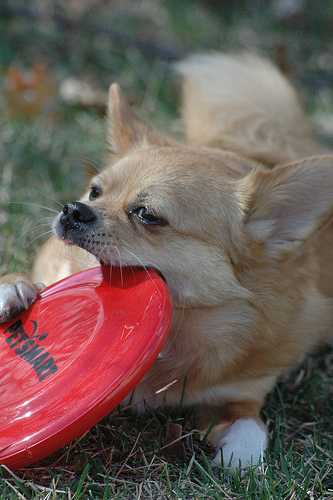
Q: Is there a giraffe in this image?
A: No, there are no giraffes.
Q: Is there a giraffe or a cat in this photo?
A: No, there are no giraffes or cats.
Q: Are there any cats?
A: No, there are no cats.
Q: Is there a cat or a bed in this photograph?
A: No, there are no cats or beds.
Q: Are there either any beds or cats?
A: No, there are no cats or beds.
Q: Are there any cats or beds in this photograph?
A: No, there are no cats or beds.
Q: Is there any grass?
A: Yes, there is grass.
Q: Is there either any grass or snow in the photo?
A: Yes, there is grass.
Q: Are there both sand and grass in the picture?
A: No, there is grass but no sand.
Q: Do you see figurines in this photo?
A: No, there are no figurines.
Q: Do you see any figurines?
A: No, there are no figurines.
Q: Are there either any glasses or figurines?
A: No, there are no figurines or glasses.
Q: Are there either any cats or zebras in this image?
A: No, there are no cats or zebras.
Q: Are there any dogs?
A: Yes, there is a dog.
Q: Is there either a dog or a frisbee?
A: Yes, there is a dog.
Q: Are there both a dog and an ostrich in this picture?
A: No, there is a dog but no ostriches.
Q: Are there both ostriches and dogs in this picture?
A: No, there is a dog but no ostriches.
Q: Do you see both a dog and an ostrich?
A: No, there is a dog but no ostriches.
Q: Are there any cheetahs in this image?
A: No, there are no cheetahs.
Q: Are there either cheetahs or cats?
A: No, there are no cheetahs or cats.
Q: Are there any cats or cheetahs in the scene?
A: No, there are no cheetahs or cats.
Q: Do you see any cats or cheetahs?
A: No, there are no cheetahs or cats.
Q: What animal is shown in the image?
A: The animal is a dog.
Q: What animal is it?
A: The animal is a dog.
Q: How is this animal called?
A: This is a dog.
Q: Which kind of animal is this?
A: This is a dog.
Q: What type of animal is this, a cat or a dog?
A: This is a dog.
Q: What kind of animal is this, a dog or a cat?
A: This is a dog.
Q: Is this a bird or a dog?
A: This is a dog.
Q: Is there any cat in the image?
A: No, there are no cats.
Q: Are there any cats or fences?
A: No, there are no cats or fences.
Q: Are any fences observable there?
A: No, there are no fences.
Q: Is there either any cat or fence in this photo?
A: No, there are no fences or cats.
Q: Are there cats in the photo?
A: No, there are no cats.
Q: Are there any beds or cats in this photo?
A: No, there are no cats or beds.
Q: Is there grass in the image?
A: Yes, there is grass.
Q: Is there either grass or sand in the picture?
A: Yes, there is grass.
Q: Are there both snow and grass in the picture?
A: No, there is grass but no snow.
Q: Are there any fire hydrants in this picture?
A: No, there are no fire hydrants.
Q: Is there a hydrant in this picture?
A: No, there are no fire hydrants.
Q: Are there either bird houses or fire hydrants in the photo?
A: No, there are no fire hydrants or bird houses.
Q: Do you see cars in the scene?
A: No, there are no cars.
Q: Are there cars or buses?
A: No, there are no cars or buses.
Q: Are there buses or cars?
A: No, there are no cars or buses.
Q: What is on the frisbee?
A: The word is on the frisbee.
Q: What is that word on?
A: The word is on the frisbee.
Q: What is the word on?
A: The word is on the frisbee.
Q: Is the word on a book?
A: No, the word is on the frisbee.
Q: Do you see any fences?
A: No, there are no fences.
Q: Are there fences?
A: No, there are no fences.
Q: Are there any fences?
A: No, there are no fences.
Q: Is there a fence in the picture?
A: No, there are no fences.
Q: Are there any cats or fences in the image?
A: No, there are no fences or cats.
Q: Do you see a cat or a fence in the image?
A: No, there are no fences or cats.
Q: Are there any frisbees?
A: Yes, there is a frisbee.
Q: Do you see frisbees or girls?
A: Yes, there is a frisbee.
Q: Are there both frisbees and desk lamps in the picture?
A: No, there is a frisbee but no desk lamps.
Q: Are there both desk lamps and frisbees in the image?
A: No, there is a frisbee but no desk lamps.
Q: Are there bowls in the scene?
A: No, there are no bowls.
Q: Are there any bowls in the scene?
A: No, there are no bowls.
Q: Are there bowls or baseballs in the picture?
A: No, there are no bowls or baseballs.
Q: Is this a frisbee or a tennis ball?
A: This is a frisbee.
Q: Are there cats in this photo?
A: No, there are no cats.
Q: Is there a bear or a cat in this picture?
A: No, there are no cats or bears.